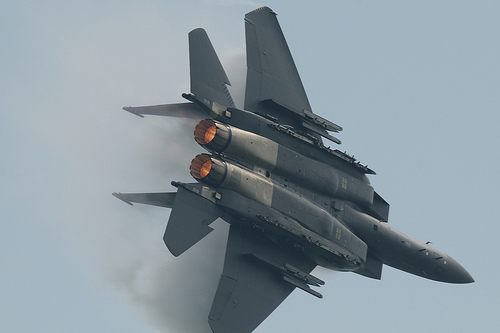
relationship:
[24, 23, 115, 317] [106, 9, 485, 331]
background behind black jet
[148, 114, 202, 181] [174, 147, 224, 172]
smoke emisison from hole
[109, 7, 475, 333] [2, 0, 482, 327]
black jet flying in sky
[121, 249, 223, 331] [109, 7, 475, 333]
smoke from black jet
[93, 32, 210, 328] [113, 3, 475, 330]
smoke from jet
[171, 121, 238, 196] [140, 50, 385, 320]
engines on jet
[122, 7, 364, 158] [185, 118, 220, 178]
ribbed wings with light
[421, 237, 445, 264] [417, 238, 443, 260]
tiny curls on top of body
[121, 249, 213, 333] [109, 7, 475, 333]
smoke from black jet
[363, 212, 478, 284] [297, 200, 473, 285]
body of rocket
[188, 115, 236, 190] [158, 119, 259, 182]
lights on jet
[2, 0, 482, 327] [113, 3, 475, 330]
sky has jet